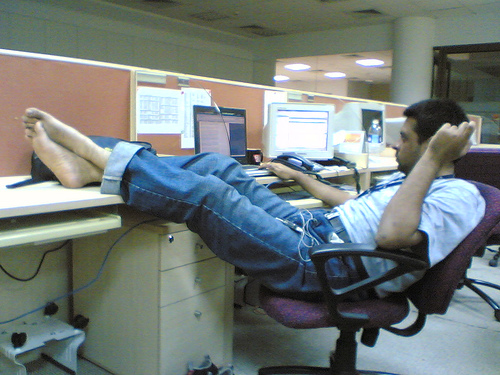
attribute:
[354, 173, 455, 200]
lanyard — blue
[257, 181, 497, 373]
chair — reclining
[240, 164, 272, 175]
keyboard — white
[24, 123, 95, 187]
foot — bare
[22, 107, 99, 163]
foot — bare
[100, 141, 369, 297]
jeans — rolled up, high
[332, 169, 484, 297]
shirt — white